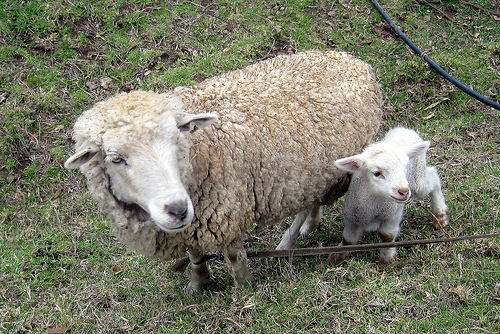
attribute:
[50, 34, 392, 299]
sheep — brown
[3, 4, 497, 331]
field — grassy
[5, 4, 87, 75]
weeds — small, dark green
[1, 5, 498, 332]
grass — green, brown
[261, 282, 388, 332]
grass — green, brown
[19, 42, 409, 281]
sheep — brown, dirty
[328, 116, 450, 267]
baby lamb — small, white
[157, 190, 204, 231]
nose — adorable, pink, black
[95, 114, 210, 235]
face — white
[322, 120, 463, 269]
sheep — white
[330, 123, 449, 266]
sheep — infant, small, beautiful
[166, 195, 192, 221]
nose — black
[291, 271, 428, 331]
grass — brown, green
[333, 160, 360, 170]
ear — white, pointed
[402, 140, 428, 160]
ear — pointed, white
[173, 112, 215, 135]
ear — pointed, white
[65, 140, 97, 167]
ear — pointed, white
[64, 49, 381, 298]
sheep — woolly brown, white, mama sheep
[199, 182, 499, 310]
rope — brown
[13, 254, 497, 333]
grass — brown, green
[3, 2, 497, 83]
grass — green, brown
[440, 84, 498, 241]
grass — brown, green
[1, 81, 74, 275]
grass — green, brown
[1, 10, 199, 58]
green grass — short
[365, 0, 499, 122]
cable — black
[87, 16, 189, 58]
grass — green, brown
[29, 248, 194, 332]
grass — dead brown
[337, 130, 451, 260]
lamb — small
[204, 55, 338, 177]
coat — brown, white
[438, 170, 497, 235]
grass — green and brown